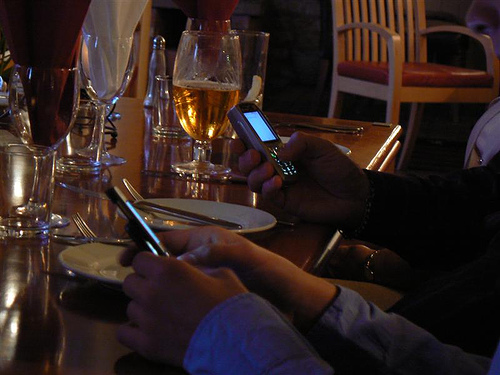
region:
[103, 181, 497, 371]
hands on the table holdings a cellphone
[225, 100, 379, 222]
cellphone in the person's hand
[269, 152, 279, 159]
green button on the cell phone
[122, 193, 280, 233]
small white plate on a table with a utensil on it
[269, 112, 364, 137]
silver utensil on a wooden table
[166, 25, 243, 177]
brown liquid in a glass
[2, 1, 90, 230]
wine glass with a burgundy napkin in it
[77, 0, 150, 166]
wine glass with a white napkin it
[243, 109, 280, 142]
phone screen display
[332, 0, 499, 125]
wooden chair with a red seat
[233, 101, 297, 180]
white cell phone in hand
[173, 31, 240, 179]
beer in clear glass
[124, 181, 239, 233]
silver metal dinner fork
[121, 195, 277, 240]
white ceramic plate on bar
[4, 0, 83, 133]
red fabric napkin in glass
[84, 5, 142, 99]
white napkin in glass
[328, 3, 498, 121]
white and red chair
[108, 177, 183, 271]
cell phone in hand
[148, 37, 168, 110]
empty bottle on table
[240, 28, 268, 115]
empty glass on table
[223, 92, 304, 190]
the cellphone is turned on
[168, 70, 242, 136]
the liquid is an amber color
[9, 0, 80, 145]
this napkin is maroon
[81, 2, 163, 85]
this napkin is white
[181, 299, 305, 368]
the shirt is blue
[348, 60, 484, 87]
the cussion is red in color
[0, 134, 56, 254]
the glass is empty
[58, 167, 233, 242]
the utensil's are silver in color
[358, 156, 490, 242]
the shirt is black in color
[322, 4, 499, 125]
the chair is a tan cream color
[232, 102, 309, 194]
cell phone in person's hand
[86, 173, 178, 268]
cell phone in person's hand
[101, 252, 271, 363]
left hand of person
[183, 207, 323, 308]
right hand of person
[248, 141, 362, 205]
right hand of person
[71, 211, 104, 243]
silver fork on table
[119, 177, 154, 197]
silver fork on table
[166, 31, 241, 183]
glass of beer on table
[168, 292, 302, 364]
blue shirt cuff on person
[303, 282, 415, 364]
blue shirt cuff on person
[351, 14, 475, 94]
a chair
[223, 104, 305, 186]
cellphone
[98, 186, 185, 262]
a man holding a cellphone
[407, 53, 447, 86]
the seat of the chair is red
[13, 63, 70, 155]
a wine glass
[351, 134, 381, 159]
a brown table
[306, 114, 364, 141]
utensils on the table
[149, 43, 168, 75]
a pepper shaker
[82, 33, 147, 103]
a wine glass with a napkin in it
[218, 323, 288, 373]
a person wearing long sleeves